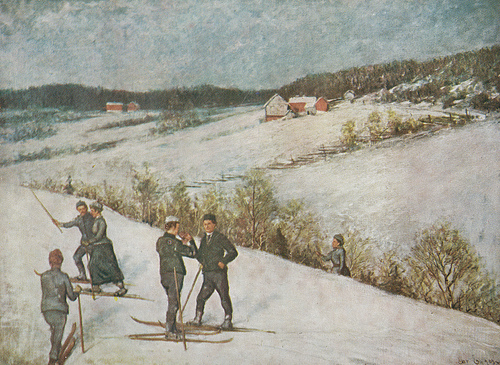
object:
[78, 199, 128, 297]
people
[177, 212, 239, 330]
man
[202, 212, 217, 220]
cap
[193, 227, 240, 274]
suit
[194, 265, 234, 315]
pants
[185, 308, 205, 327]
boots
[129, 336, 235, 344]
skiis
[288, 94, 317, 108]
barn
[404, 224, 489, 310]
trees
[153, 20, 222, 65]
clouds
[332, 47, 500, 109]
mountain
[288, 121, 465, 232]
field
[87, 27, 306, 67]
sky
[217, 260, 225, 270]
hands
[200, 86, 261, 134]
farm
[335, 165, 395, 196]
snow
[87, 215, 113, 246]
clothes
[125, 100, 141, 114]
house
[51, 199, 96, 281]
man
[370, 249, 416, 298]
bush